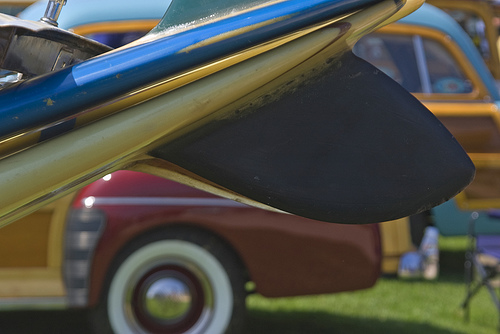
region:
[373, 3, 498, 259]
a blue and yellow car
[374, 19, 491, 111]
window frame is yellow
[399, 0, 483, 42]
roof of car is blue and yellow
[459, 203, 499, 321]
purple folding chair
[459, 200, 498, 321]
armrest of chair is purple and silver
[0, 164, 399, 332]
part of a yellow and red car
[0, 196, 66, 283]
door of car is yellow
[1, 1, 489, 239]
two surfboards on a car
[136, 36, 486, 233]
fin of a yellow surfboard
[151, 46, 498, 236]
fin of surfboard is blue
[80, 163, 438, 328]
Vintage red automobile in background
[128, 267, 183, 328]
Silver hubcap on tire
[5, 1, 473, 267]
blue and yellow surfboard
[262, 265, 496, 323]
mowed green grass under cars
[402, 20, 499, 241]
Blue automobile in background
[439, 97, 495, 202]
wooden panels on blue car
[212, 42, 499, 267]
lower blue fin of surfboard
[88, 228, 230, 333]
White wall of tire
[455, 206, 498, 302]
Blue fold out chair on grass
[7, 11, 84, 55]
chrome top above surfboard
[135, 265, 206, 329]
the red inner trim on a car's tire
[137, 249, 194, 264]
the white painted section of a white wall tire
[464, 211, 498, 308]
a folding metal chair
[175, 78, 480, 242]
the bottom of a black tail fin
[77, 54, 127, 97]
a section of metallic blue metal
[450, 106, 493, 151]
wood paneling on an antique station wagon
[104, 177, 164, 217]
a silver stripe on the back of a red car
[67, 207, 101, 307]
a silver striped section in front of the back tire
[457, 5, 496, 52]
a yellow framed window on a large vehicle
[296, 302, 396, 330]
the dark shadow of a car on the grass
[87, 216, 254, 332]
a wheel in the back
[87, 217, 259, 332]
the tire of a wheel is black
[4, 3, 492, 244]
a car carrying surfboards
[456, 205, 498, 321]
purple chair over the grass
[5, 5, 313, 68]
a surfboard is blue and yellow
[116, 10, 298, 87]
side of the surfboard has yellow stripe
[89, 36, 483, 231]
yellow surfboard has blue fin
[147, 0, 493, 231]
fins on back of surfboards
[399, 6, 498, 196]
a yellow and blue car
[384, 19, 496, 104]
window of car has yellow frame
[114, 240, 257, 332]
the wheel is circle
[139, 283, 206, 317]
middle of the wheel is silver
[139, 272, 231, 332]
reflection in the wheel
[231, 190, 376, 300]
the hub is red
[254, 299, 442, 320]
shadow on the ground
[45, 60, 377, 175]
the fixture is chromw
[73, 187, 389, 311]
the vehicle is shiny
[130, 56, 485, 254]
the tail is on fixture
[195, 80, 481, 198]
the tail is dark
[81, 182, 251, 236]
line on the car